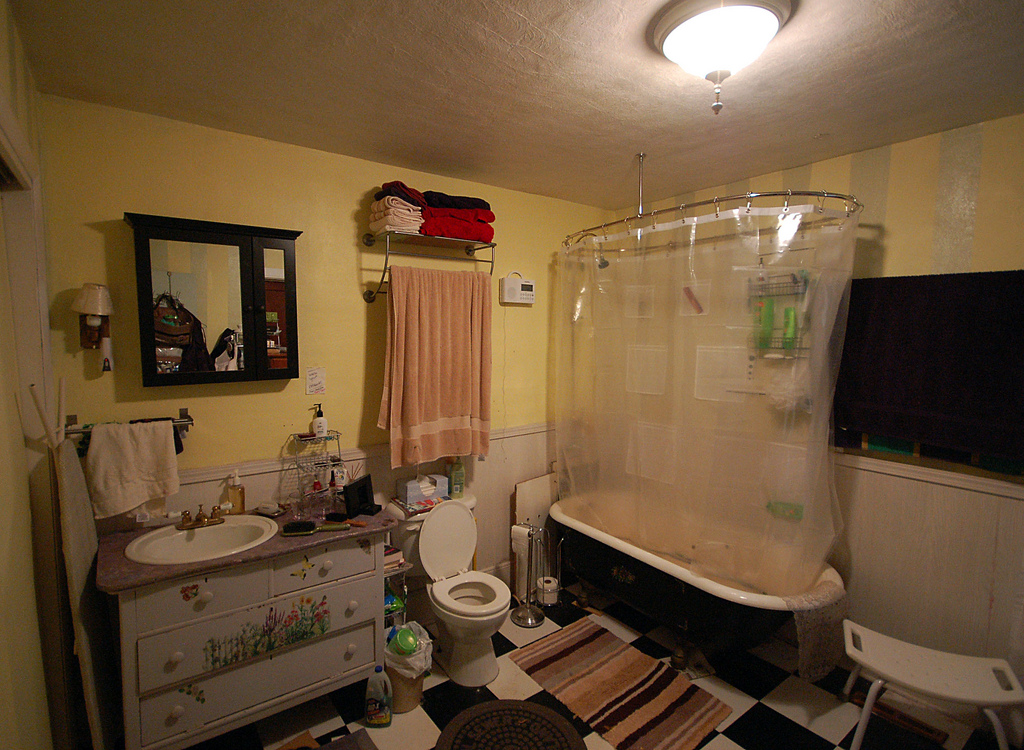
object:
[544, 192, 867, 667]
shower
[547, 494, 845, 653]
bathtub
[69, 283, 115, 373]
light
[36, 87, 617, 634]
wall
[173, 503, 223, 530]
faucet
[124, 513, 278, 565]
sink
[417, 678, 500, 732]
tile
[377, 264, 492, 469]
towel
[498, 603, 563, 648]
tile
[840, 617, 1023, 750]
stool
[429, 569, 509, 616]
toilet seat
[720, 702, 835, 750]
tile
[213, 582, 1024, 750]
floor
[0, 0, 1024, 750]
bathroom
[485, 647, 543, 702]
tile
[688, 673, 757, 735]
tile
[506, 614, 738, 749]
rug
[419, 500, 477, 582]
lid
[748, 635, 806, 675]
tile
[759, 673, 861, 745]
tile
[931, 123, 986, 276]
tile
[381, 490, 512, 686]
toilet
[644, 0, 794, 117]
light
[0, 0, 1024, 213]
ceiling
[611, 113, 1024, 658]
wall